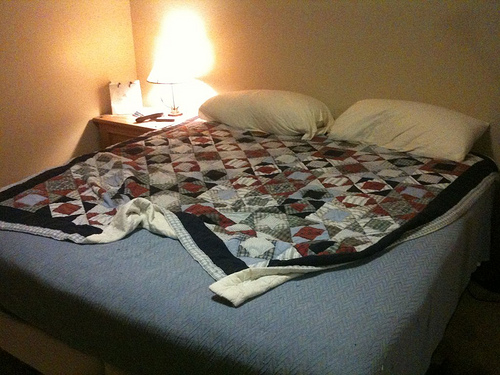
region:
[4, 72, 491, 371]
this is a large bed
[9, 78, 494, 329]
this is a quilt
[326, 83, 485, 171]
this is a pillow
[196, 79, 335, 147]
a white pillow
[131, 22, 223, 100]
the lamp is bright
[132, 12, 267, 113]
the lamp is on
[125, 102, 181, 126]
television remote controls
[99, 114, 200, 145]
a bedside drawer table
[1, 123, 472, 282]
a patterned quilt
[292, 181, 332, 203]
a black square on the quilt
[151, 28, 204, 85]
white lamp shade on lamp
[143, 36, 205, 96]
orange light from lamp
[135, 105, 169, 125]
black remotes on entable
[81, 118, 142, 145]
brown wooden entable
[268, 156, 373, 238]
multi colored quilt on bed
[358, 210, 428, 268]
black lining of quilt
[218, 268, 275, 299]
white bottom of quilt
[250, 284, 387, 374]
blue sheet below quilt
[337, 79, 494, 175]
white pillow case on pillow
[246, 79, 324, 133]
white pillow on bed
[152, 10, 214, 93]
lamp shade for lamp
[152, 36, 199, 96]
bright orange lamp light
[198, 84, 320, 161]
white pillow on bed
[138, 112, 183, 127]
black remotes on entable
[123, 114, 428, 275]
quilt on top of bed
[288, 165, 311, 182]
red and white quilt on bed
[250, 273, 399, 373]
blue bottom sheet to quilt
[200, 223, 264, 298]
black boarder of quilt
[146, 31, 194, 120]
a lamp on a nightstand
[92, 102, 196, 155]
a nightstand next to a bed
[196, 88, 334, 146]
a white pillow on a bed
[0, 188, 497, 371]
a blue blanket on a bed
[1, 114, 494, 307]
a quilt on a bed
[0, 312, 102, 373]
a white box spring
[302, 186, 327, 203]
a navy square on a quilt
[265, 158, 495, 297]
a navy border on a quilt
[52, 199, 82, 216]
a red square on a quilt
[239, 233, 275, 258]
a white square on a quilt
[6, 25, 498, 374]
bed has rumpled quilt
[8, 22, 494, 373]
bed has two white pillows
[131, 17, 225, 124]
bedside lamp is turned on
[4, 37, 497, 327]
quilt has a white underside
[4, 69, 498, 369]
blue blanket is on the bed under the quilt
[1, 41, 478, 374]
rumpled pillows are on the bed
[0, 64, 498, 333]
quilt has multiple colors and designs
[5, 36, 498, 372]
bed is not freshly made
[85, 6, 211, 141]
bedside table holds a lamp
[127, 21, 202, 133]
lamp has a white lamp shade